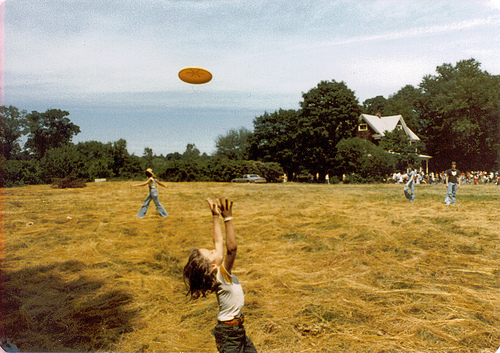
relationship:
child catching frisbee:
[183, 198, 257, 353] [177, 67, 214, 83]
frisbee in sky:
[177, 67, 214, 83] [1, 1, 499, 157]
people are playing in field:
[130, 161, 499, 352] [0, 179, 499, 352]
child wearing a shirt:
[183, 198, 257, 353] [212, 261, 246, 321]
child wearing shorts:
[183, 198, 257, 353] [211, 316, 255, 352]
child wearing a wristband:
[183, 198, 257, 353] [223, 216, 232, 222]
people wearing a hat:
[130, 168, 172, 220] [145, 168, 155, 179]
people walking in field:
[130, 168, 172, 220] [0, 179, 499, 352]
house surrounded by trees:
[353, 112, 432, 175] [247, 58, 499, 183]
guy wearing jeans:
[402, 167, 417, 200] [403, 179, 415, 200]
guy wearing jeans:
[445, 161, 462, 205] [445, 184, 457, 204]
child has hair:
[183, 198, 257, 353] [181, 247, 221, 299]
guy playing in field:
[402, 167, 417, 200] [0, 179, 499, 352]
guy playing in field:
[445, 161, 462, 205] [0, 179, 499, 352]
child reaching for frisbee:
[183, 198, 257, 353] [177, 67, 214, 83]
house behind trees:
[353, 112, 432, 175] [245, 81, 426, 184]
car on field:
[231, 173, 266, 183] [0, 179, 499, 352]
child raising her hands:
[183, 198, 257, 353] [204, 196, 234, 215]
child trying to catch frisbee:
[183, 198, 257, 353] [177, 67, 214, 83]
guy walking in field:
[402, 167, 417, 200] [0, 179, 499, 352]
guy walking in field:
[445, 161, 462, 205] [0, 179, 499, 352]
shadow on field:
[0, 258, 148, 352] [0, 179, 499, 352]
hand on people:
[131, 185, 136, 189] [130, 168, 172, 220]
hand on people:
[165, 184, 169, 187] [130, 168, 172, 220]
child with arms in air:
[183, 198, 257, 353] [208, 215, 237, 272]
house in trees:
[353, 112, 432, 175] [247, 58, 499, 183]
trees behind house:
[356, 58, 499, 172] [353, 112, 432, 175]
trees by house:
[247, 58, 499, 183] [353, 112, 432, 175]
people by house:
[395, 168, 499, 185] [353, 112, 432, 175]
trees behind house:
[247, 58, 499, 183] [353, 112, 432, 175]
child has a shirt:
[183, 198, 257, 353] [212, 261, 246, 321]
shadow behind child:
[0, 258, 148, 352] [183, 198, 257, 353]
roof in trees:
[358, 113, 421, 141] [247, 58, 499, 183]